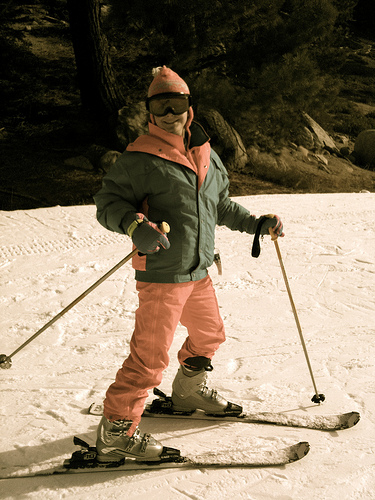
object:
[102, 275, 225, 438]
snow pants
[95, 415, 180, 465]
ski boot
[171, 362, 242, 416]
ski boot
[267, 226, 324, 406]
ski pole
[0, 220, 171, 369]
ski pole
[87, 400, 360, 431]
ski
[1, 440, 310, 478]
ski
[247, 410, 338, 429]
snow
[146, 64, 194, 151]
hat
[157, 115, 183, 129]
smile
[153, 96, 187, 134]
face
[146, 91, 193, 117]
goggles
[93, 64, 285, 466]
skier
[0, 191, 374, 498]
snow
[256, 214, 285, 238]
hand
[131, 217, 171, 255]
hand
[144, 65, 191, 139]
head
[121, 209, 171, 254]
glove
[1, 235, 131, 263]
tracks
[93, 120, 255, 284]
jacket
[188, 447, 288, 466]
snow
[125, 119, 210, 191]
trim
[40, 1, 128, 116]
tree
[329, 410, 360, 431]
tip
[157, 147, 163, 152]
button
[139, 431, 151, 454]
clasp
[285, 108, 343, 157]
boulder